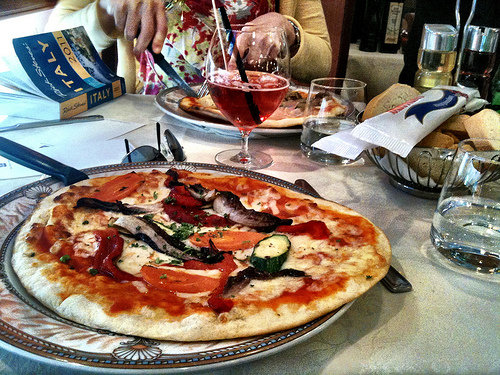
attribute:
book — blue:
[8, 22, 143, 119]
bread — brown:
[370, 74, 498, 147]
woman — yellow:
[93, 1, 347, 109]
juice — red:
[176, 51, 322, 138]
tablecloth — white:
[116, 87, 182, 192]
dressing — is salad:
[417, 19, 498, 118]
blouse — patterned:
[131, 1, 231, 78]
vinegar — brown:
[450, 5, 495, 122]